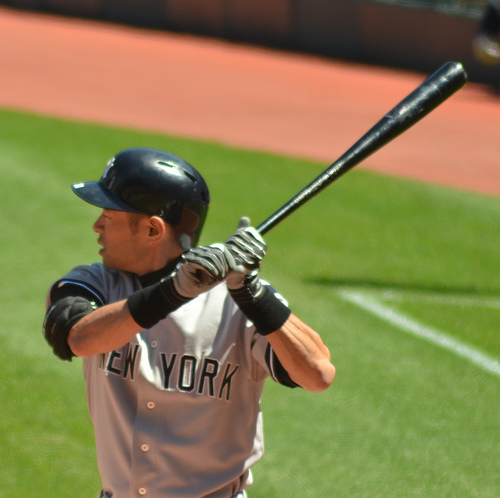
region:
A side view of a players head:
[63, 143, 221, 288]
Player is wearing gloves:
[151, 210, 281, 315]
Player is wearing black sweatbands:
[115, 270, 290, 356]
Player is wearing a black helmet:
[65, 145, 220, 260]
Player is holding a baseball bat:
[165, 40, 470, 312]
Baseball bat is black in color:
[250, 56, 471, 271]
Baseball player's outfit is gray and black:
[26, 232, 301, 495]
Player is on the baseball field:
[5, 126, 490, 496]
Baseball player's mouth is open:
[87, 230, 130, 265]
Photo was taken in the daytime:
[7, 11, 498, 494]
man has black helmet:
[92, 152, 235, 264]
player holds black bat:
[195, 42, 459, 284]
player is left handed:
[172, 53, 464, 325]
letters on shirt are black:
[54, 313, 247, 395]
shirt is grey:
[70, 270, 228, 480]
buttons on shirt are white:
[108, 326, 154, 492]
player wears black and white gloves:
[162, 233, 281, 305]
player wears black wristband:
[252, 273, 303, 354]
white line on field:
[314, 249, 496, 405]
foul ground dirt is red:
[124, 44, 474, 223]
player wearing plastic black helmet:
[61, 130, 208, 272]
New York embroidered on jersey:
[88, 330, 241, 406]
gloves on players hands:
[120, 210, 297, 346]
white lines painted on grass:
[334, 268, 489, 396]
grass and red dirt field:
[217, 98, 307, 173]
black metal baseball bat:
[206, 41, 477, 263]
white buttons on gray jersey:
[113, 398, 158, 496]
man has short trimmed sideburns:
[123, 212, 148, 262]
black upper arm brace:
[28, 294, 98, 369]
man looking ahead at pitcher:
[58, 117, 205, 299]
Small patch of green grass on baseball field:
[390, 380, 419, 421]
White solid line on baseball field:
[418, 320, 453, 352]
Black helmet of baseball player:
[126, 159, 193, 199]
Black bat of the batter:
[307, 115, 407, 195]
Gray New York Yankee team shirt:
[148, 340, 236, 456]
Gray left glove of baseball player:
[183, 250, 222, 295]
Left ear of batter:
[146, 216, 171, 253]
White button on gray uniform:
[146, 400, 157, 420]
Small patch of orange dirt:
[249, 73, 286, 98]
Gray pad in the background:
[301, 11, 341, 44]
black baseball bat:
[192, 55, 472, 291]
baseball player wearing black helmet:
[71, 137, 215, 281]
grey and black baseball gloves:
[171, 216, 271, 303]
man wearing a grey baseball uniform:
[38, 146, 335, 496]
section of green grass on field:
[378, 358, 493, 483]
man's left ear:
[143, 207, 170, 245]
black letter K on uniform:
[217, 358, 242, 405]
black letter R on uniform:
[196, 353, 224, 401]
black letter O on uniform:
[178, 349, 200, 396]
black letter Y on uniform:
[158, 351, 180, 391]